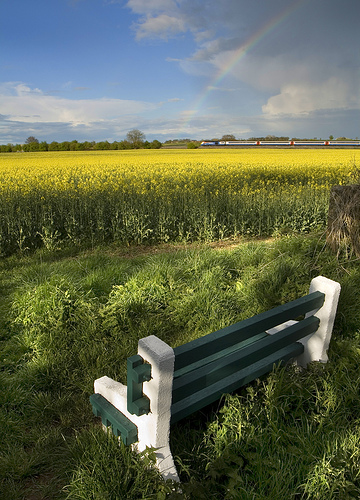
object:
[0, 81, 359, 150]
distance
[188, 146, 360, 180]
ground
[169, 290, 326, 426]
sticks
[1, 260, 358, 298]
grass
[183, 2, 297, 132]
rainbow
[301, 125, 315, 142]
ground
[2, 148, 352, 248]
plants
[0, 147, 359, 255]
flowers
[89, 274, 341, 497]
bench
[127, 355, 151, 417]
green side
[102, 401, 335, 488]
grass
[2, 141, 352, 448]
field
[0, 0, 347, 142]
sky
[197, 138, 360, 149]
train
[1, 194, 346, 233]
grass